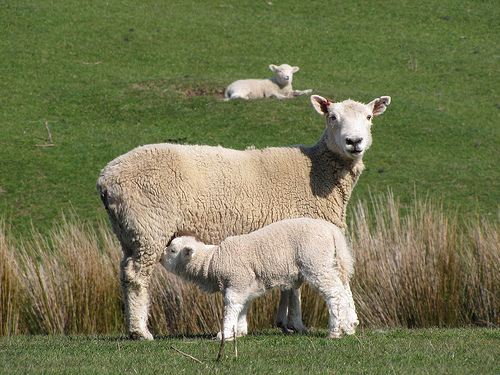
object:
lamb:
[158, 217, 361, 339]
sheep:
[94, 94, 393, 340]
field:
[1, 0, 498, 371]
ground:
[83, 100, 298, 130]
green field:
[0, 0, 500, 245]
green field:
[0, 327, 499, 374]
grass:
[17, 9, 499, 330]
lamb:
[222, 61, 312, 101]